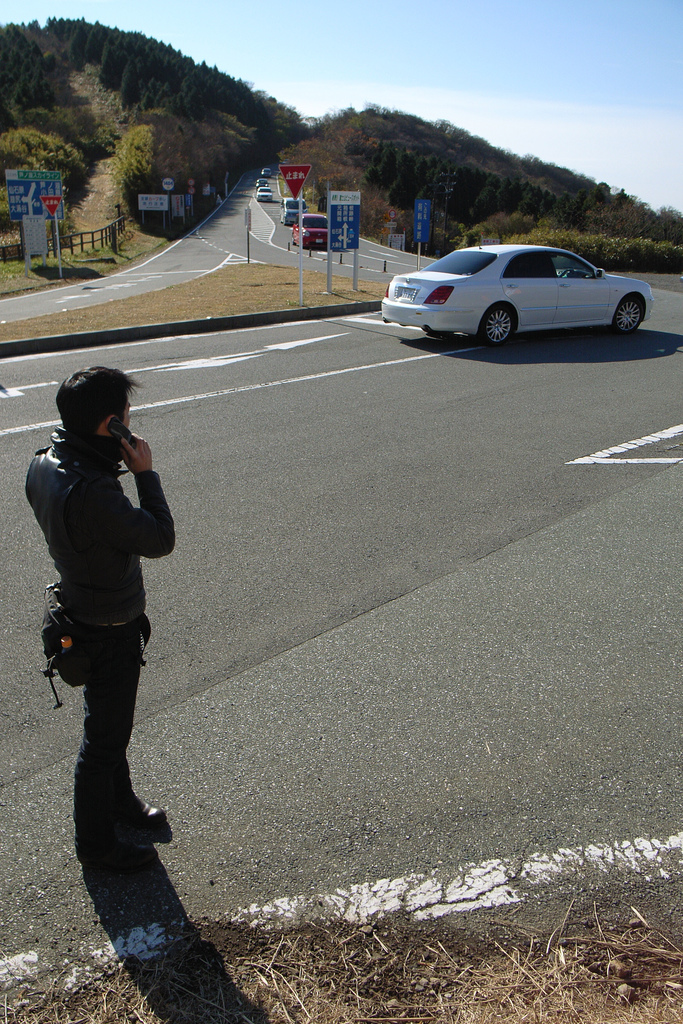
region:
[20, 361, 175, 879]
A man standing on a road.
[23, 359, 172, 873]
A man standing talking on a phone.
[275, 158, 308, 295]
A red sign on a pole.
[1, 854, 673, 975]
A white line on black top.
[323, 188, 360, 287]
A blue and white sign on post.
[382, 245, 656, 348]
A white car in a turning lane.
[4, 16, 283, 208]
A hill covered in trees.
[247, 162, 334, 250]
Cars coming down a hill.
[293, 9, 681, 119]
A clear blue sky above the hills.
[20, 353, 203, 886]
man is standing in road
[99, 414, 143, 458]
man holding phone to ear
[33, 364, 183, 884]
man talking on phone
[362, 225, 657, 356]
small car driving in road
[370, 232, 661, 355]
small car is white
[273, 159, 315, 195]
sign is red and white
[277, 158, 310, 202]
red sign is triangle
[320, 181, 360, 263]
large sign in grass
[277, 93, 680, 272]
small hillside on right side of road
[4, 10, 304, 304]
small hill on right side of road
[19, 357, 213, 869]
man has black clothes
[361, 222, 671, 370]
the car is white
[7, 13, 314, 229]
the hill is covered with trees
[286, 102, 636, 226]
the hill is covered with trees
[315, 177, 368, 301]
the sign is white and blue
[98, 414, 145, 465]
the cell phone is black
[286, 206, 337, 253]
the car is red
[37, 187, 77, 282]
a sign color red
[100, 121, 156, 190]
the trees are on side the road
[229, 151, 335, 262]
cars on the road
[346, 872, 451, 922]
a white line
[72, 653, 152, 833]
man wearing pants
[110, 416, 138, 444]
a cellphone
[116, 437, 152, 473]
man holding a cellphone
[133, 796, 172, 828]
a black shoe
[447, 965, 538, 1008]
weeds in the dirt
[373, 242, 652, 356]
a white car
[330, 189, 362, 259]
a sign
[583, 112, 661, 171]
a white cloud in the sky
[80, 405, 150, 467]
the ear of a young man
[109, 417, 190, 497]
the hand of a young man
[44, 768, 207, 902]
the feet of a young man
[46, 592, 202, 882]
the legs of a young man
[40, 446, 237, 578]
the arm of a young man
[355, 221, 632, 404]
a white car on the road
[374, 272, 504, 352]
the tail light of a car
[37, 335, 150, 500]
the hair of a young man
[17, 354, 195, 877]
person standing on the street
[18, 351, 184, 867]
person on the phone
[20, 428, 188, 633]
dark colored leather jacket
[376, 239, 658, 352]
white car on the street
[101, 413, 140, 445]
cell phone in a person's hand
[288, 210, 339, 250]
red car in the street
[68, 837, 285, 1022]
shadow of a man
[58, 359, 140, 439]
dark hair of a person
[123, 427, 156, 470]
right hand holding a cell phone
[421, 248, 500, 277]
tinted back window of a white car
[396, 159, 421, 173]
green leaves on the tree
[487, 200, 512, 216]
green leaves on the tree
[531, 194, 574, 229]
green leaves on the tree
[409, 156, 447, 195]
green leaves on the tree